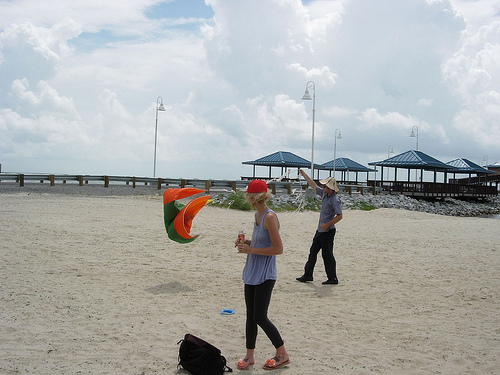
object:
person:
[233, 177, 294, 370]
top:
[236, 210, 283, 287]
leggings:
[240, 279, 282, 350]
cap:
[238, 177, 269, 195]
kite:
[160, 185, 212, 244]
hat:
[317, 175, 341, 193]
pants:
[296, 227, 340, 283]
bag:
[173, 332, 238, 374]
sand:
[1, 193, 497, 375]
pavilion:
[367, 145, 467, 206]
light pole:
[302, 79, 316, 202]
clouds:
[2, 0, 499, 78]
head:
[243, 178, 272, 208]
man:
[296, 166, 348, 288]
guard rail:
[0, 174, 390, 194]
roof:
[368, 150, 461, 170]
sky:
[1, 2, 499, 80]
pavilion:
[241, 150, 325, 192]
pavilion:
[320, 155, 378, 192]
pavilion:
[436, 154, 496, 189]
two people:
[235, 168, 350, 371]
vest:
[313, 185, 344, 233]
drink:
[238, 232, 246, 246]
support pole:
[251, 166, 257, 179]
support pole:
[379, 166, 384, 182]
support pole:
[433, 169, 438, 182]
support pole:
[268, 165, 272, 178]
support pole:
[393, 167, 398, 182]